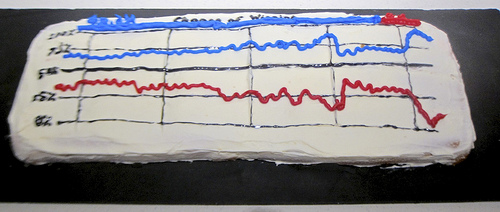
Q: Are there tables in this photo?
A: Yes, there is a table.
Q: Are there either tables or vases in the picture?
A: Yes, there is a table.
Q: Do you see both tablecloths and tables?
A: No, there is a table but no tablecloths.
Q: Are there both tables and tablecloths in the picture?
A: No, there is a table but no tablecloths.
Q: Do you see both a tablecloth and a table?
A: No, there is a table but no tablecloths.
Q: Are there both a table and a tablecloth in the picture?
A: No, there is a table but no tablecloths.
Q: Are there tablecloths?
A: No, there are no tablecloths.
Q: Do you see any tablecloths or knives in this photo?
A: No, there are no tablecloths or knives.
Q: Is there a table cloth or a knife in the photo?
A: No, there are no tablecloths or knives.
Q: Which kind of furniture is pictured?
A: The furniture is a table.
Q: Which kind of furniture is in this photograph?
A: The furniture is a table.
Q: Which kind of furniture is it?
A: The piece of furniture is a table.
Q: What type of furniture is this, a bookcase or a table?
A: This is a table.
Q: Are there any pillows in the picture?
A: No, there are no pillows.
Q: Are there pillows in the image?
A: No, there are no pillows.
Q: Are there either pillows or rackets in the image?
A: No, there are no pillows or rackets.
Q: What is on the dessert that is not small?
A: The frosting is on the cake.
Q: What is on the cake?
A: The frosting is on the cake.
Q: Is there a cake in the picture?
A: Yes, there is a cake.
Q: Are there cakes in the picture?
A: Yes, there is a cake.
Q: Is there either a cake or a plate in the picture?
A: Yes, there is a cake.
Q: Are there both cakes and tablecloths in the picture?
A: No, there is a cake but no tablecloths.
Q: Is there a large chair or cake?
A: Yes, there is a large cake.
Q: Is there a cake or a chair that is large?
A: Yes, the cake is large.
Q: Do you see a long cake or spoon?
A: Yes, there is a long cake.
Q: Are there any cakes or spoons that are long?
A: Yes, the cake is long.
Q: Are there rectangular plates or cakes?
A: Yes, there is a rectangular cake.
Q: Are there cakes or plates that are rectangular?
A: Yes, the cake is rectangular.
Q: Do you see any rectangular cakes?
A: Yes, there is a rectangular cake.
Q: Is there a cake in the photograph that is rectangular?
A: Yes, there is a cake that is rectangular.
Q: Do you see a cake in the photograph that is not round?
A: Yes, there is a rectangular cake.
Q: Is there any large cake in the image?
A: Yes, there is a large cake.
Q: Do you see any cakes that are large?
A: Yes, there is a large cake.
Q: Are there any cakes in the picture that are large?
A: Yes, there is a cake that is large.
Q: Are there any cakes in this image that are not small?
A: Yes, there is a large cake.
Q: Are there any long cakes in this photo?
A: Yes, there is a long cake.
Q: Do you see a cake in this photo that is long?
A: Yes, there is a cake that is long.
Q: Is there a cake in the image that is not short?
A: Yes, there is a long cake.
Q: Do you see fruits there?
A: No, there are no fruits.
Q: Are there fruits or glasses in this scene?
A: No, there are no fruits or glasses.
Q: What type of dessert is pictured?
A: The dessert is a cake.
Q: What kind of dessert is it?
A: The dessert is a cake.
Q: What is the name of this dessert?
A: This is a cake.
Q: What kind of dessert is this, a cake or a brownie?
A: This is a cake.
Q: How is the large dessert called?
A: The dessert is a cake.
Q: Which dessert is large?
A: The dessert is a cake.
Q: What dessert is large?
A: The dessert is a cake.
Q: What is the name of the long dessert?
A: The dessert is a cake.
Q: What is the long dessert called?
A: The dessert is a cake.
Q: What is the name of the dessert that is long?
A: The dessert is a cake.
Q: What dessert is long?
A: The dessert is a cake.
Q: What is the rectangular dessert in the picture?
A: The dessert is a cake.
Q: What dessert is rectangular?
A: The dessert is a cake.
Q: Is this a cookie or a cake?
A: This is a cake.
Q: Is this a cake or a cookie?
A: This is a cake.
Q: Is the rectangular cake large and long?
A: Yes, the cake is large and long.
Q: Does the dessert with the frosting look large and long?
A: Yes, the cake is large and long.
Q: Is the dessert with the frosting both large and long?
A: Yes, the cake is large and long.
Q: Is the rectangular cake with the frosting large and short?
A: No, the cake is large but long.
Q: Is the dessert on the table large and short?
A: No, the cake is large but long.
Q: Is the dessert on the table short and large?
A: No, the cake is large but long.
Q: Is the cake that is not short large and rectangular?
A: Yes, the cake is large and rectangular.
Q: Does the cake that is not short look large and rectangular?
A: Yes, the cake is large and rectangular.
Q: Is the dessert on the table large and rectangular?
A: Yes, the cake is large and rectangular.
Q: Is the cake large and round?
A: No, the cake is large but rectangular.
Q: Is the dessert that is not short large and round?
A: No, the cake is large but rectangular.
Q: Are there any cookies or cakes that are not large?
A: No, there is a cake but it is large.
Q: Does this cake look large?
A: Yes, the cake is large.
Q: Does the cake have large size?
A: Yes, the cake is large.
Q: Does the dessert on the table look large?
A: Yes, the cake is large.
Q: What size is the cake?
A: The cake is large.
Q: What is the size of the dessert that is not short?
A: The cake is large.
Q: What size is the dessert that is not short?
A: The cake is large.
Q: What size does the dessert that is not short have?
A: The cake has large size.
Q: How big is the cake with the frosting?
A: The cake is large.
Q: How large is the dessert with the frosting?
A: The cake is large.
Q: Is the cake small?
A: No, the cake is large.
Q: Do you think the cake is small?
A: No, the cake is large.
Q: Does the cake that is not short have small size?
A: No, the cake is large.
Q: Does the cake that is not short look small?
A: No, the cake is large.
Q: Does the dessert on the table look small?
A: No, the cake is large.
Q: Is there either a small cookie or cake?
A: No, there is a cake but it is large.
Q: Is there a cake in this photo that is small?
A: No, there is a cake but it is large.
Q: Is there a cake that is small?
A: No, there is a cake but it is large.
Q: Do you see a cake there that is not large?
A: No, there is a cake but it is large.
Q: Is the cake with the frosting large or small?
A: The cake is large.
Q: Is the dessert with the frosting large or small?
A: The cake is large.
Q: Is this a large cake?
A: Yes, this is a large cake.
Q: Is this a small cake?
A: No, this is a large cake.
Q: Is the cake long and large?
A: Yes, the cake is long and large.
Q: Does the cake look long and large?
A: Yes, the cake is long and large.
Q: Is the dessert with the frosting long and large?
A: Yes, the cake is long and large.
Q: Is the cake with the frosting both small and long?
A: No, the cake is long but large.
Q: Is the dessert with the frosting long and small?
A: No, the cake is long but large.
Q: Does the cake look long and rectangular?
A: Yes, the cake is long and rectangular.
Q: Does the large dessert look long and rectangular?
A: Yes, the cake is long and rectangular.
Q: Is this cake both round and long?
A: No, the cake is long but rectangular.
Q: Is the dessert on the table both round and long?
A: No, the cake is long but rectangular.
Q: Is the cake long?
A: Yes, the cake is long.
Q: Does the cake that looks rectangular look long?
A: Yes, the cake is long.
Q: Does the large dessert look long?
A: Yes, the cake is long.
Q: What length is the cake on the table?
A: The cake is long.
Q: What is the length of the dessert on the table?
A: The cake is long.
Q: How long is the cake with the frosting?
A: The cake is long.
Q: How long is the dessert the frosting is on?
A: The cake is long.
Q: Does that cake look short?
A: No, the cake is long.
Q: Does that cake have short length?
A: No, the cake is long.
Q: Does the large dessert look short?
A: No, the cake is long.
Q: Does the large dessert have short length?
A: No, the cake is long.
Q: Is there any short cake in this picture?
A: No, there is a cake but it is long.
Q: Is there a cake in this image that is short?
A: No, there is a cake but it is long.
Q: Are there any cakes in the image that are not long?
A: No, there is a cake but it is long.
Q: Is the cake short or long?
A: The cake is long.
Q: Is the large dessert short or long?
A: The cake is long.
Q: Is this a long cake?
A: Yes, this is a long cake.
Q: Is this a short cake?
A: No, this is a long cake.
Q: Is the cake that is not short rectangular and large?
A: Yes, the cake is rectangular and large.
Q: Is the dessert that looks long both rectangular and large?
A: Yes, the cake is rectangular and large.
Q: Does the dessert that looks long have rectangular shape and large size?
A: Yes, the cake is rectangular and large.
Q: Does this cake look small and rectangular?
A: No, the cake is rectangular but large.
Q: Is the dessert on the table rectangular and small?
A: No, the cake is rectangular but large.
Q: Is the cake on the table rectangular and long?
A: Yes, the cake is rectangular and long.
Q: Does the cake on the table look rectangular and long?
A: Yes, the cake is rectangular and long.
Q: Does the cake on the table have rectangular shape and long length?
A: Yes, the cake is rectangular and long.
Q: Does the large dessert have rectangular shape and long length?
A: Yes, the cake is rectangular and long.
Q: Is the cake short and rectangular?
A: No, the cake is rectangular but long.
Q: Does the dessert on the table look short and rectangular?
A: No, the cake is rectangular but long.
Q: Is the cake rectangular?
A: Yes, the cake is rectangular.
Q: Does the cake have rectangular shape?
A: Yes, the cake is rectangular.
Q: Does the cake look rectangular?
A: Yes, the cake is rectangular.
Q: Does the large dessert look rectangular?
A: Yes, the cake is rectangular.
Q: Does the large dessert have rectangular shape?
A: Yes, the cake is rectangular.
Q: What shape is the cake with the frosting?
A: The cake is rectangular.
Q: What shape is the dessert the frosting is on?
A: The cake is rectangular.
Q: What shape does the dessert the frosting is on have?
A: The cake has rectangular shape.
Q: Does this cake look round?
A: No, the cake is rectangular.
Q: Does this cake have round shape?
A: No, the cake is rectangular.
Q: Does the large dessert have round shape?
A: No, the cake is rectangular.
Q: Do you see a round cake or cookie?
A: No, there is a cake but it is rectangular.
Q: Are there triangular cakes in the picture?
A: No, there is a cake but it is rectangular.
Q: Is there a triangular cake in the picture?
A: No, there is a cake but it is rectangular.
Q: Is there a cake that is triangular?
A: No, there is a cake but it is rectangular.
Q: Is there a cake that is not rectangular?
A: No, there is a cake but it is rectangular.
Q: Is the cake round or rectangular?
A: The cake is rectangular.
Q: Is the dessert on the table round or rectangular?
A: The cake is rectangular.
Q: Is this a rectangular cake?
A: Yes, this is a rectangular cake.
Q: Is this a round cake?
A: No, this is a rectangular cake.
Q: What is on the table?
A: The cake is on the table.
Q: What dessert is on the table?
A: The dessert is a cake.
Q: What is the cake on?
A: The cake is on the table.